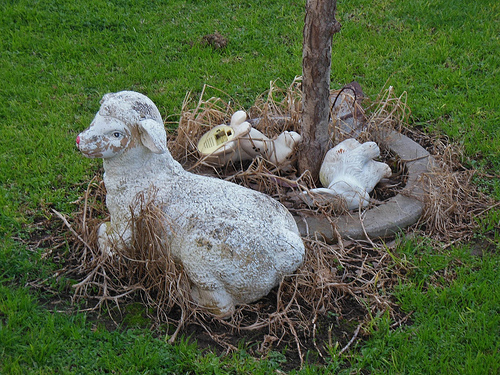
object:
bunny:
[197, 110, 301, 171]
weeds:
[137, 213, 193, 327]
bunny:
[299, 138, 393, 211]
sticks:
[278, 220, 396, 297]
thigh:
[183, 230, 274, 305]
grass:
[340, 7, 498, 93]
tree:
[297, 0, 341, 180]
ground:
[0, 0, 499, 375]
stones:
[188, 115, 438, 242]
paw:
[364, 142, 381, 159]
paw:
[379, 163, 393, 177]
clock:
[75, 90, 304, 320]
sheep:
[75, 90, 305, 319]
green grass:
[92, 29, 446, 66]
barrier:
[196, 115, 440, 242]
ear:
[299, 188, 337, 207]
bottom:
[197, 124, 234, 154]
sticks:
[258, 177, 390, 214]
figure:
[75, 90, 305, 319]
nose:
[75, 136, 80, 145]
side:
[299, 138, 392, 211]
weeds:
[317, 252, 359, 316]